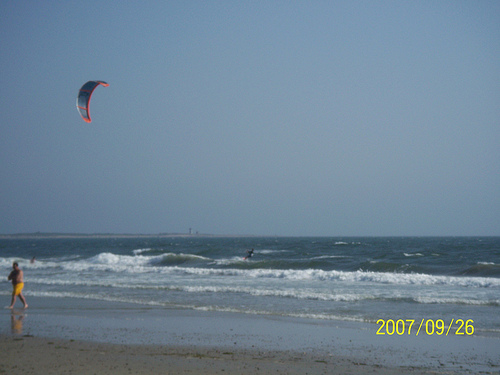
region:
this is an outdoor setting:
[22, 30, 469, 344]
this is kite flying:
[7, 37, 158, 178]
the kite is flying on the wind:
[8, 32, 169, 172]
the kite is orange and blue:
[51, 65, 151, 150]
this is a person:
[0, 215, 45, 325]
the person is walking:
[8, 255, 39, 332]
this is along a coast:
[27, 218, 328, 369]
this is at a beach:
[80, 215, 307, 358]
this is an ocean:
[160, 222, 380, 312]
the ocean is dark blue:
[224, 234, 370, 284]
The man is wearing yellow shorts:
[11, 282, 23, 296]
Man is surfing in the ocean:
[242, 246, 257, 266]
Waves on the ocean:
[95, 250, 208, 277]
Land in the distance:
[7, 227, 227, 240]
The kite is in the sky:
[75, 78, 112, 125]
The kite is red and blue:
[72, 78, 111, 125]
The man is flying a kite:
[2, 254, 32, 311]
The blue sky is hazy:
[190, 101, 357, 191]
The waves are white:
[90, 252, 148, 271]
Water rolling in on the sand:
[143, 295, 275, 325]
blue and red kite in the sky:
[59, 65, 121, 139]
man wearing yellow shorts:
[4, 283, 28, 294]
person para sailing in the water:
[238, 239, 260, 263]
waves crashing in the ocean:
[90, 240, 228, 287]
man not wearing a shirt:
[6, 257, 28, 285]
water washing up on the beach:
[143, 249, 438, 354]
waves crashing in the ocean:
[323, 223, 378, 258]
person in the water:
[236, 243, 257, 264]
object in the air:
[49, 45, 136, 146]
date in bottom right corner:
[356, 302, 487, 355]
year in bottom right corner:
[348, 306, 425, 360]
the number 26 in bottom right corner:
[446, 302, 488, 349]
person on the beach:
[4, 242, 58, 309]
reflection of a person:
[6, 305, 33, 335]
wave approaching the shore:
[82, 236, 215, 302]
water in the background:
[340, 212, 465, 280]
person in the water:
[216, 233, 277, 293]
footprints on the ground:
[50, 317, 120, 374]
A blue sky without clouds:
[3, 3, 490, 243]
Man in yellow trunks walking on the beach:
[7, 261, 31, 311]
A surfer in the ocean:
[244, 245, 255, 260]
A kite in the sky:
[75, 79, 110, 122]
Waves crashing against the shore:
[4, 250, 498, 295]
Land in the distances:
[4, 221, 261, 239]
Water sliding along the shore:
[3, 290, 416, 329]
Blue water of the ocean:
[2, 237, 496, 304]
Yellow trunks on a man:
[12, 283, 25, 294]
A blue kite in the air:
[76, 79, 106, 119]